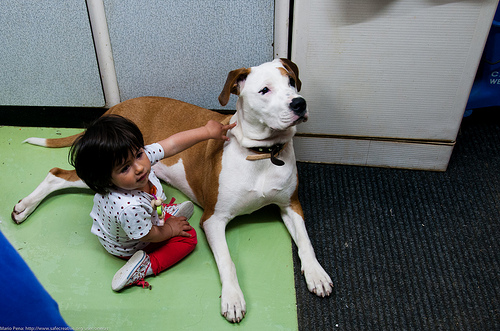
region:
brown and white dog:
[192, 51, 334, 303]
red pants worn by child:
[127, 190, 202, 277]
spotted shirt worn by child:
[68, 173, 148, 278]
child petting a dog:
[40, 31, 382, 303]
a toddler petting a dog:
[34, 54, 343, 324]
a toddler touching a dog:
[30, 25, 407, 304]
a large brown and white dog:
[19, 50, 374, 311]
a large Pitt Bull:
[16, 58, 432, 305]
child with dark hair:
[45, 89, 259, 311]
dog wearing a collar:
[202, 48, 347, 195]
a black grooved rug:
[274, 148, 492, 329]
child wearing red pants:
[51, 93, 218, 307]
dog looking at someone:
[175, 40, 372, 207]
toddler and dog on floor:
[11, 57, 331, 324]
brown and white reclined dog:
[11, 59, 336, 326]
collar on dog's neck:
[223, 113, 295, 165]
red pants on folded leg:
[147, 211, 197, 274]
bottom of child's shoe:
[112, 251, 149, 291]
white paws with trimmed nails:
[221, 266, 335, 323]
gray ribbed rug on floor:
[293, 104, 495, 329]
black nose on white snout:
[274, 94, 306, 129]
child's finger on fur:
[149, 115, 238, 167]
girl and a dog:
[8, 53, 338, 326]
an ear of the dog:
[215, 58, 248, 110]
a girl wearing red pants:
[61, 110, 241, 299]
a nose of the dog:
[286, 93, 307, 113]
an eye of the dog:
[256, 85, 272, 97]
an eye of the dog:
[286, 75, 296, 87]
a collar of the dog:
[243, 140, 290, 167]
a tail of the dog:
[18, 123, 68, 157]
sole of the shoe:
[108, 248, 145, 294]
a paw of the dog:
[218, 290, 249, 327]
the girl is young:
[69, 115, 238, 292]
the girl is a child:
[69, 115, 236, 293]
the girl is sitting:
[69, 112, 237, 292]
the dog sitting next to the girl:
[11, 57, 333, 324]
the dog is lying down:
[12, 56, 334, 322]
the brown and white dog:
[11, 57, 334, 324]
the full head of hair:
[67, 112, 153, 197]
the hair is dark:
[67, 113, 146, 198]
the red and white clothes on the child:
[69, 107, 239, 292]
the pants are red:
[152, 232, 198, 276]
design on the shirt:
[90, 198, 145, 239]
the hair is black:
[77, 132, 124, 189]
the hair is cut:
[75, 133, 130, 188]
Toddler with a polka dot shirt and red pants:
[69, 115, 239, 295]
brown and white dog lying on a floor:
[9, 58, 331, 324]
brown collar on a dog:
[239, 141, 286, 166]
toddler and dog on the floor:
[11, 56, 336, 323]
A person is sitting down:
[62, 102, 225, 297]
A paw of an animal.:
[207, 285, 244, 322]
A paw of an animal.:
[293, 257, 344, 303]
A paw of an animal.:
[14, 195, 34, 223]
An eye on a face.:
[258, 83, 272, 98]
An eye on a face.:
[286, 76, 296, 88]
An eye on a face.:
[113, 162, 132, 174]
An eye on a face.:
[132, 150, 144, 163]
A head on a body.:
[66, 107, 152, 190]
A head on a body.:
[221, 54, 312, 146]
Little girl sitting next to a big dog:
[11, 55, 336, 325]